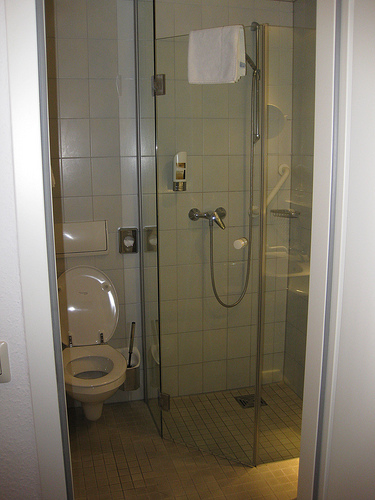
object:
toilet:
[56, 262, 127, 422]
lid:
[55, 262, 121, 346]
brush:
[126, 318, 138, 366]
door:
[150, 23, 267, 470]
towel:
[186, 26, 248, 84]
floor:
[66, 379, 305, 499]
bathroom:
[6, 2, 355, 497]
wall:
[152, 0, 295, 405]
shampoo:
[173, 149, 189, 192]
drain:
[233, 387, 270, 412]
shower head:
[243, 56, 259, 151]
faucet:
[187, 206, 226, 229]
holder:
[118, 347, 143, 391]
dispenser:
[118, 223, 142, 254]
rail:
[249, 153, 300, 217]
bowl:
[63, 375, 126, 421]